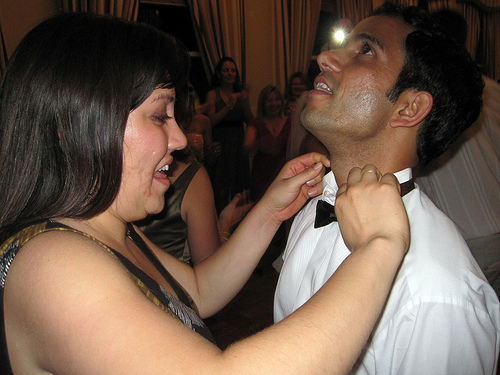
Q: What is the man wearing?
A: Person wearing white shirt.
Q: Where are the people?
A: In a room.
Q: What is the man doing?
A: Looking up.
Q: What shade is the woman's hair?
A: Brown.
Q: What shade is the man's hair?
A: Brown.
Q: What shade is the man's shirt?
A: White.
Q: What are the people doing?
A: Clapping.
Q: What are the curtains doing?
A: Hanging by the window.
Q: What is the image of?
A: Dance party.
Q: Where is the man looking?
A: Up.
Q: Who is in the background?
A: Ladies.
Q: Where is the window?
A: Behind the curtains.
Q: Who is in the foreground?
A: A man and woman?.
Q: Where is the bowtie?
A: Around the man's neck.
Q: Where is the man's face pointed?
A: Up.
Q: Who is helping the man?
A: The woman.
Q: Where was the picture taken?
A: At a dance.